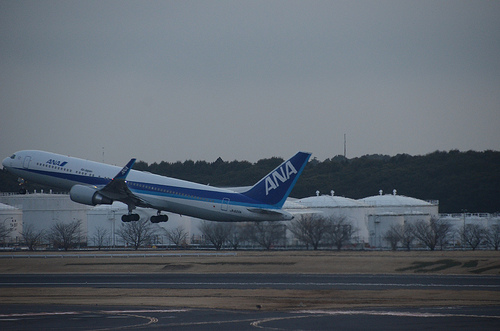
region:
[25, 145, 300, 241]
blue and white plane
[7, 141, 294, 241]
plane is taking off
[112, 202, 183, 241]
plane has black wheels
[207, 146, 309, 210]
blue and white tail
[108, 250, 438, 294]
runway is dark grey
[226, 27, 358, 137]
grey and hazy sky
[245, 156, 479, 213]
green trees behind plane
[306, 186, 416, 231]
white dome shaped buildings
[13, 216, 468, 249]
bare trees in front of domes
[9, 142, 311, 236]
the plane taking off the runway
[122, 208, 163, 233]
the landing gear of the plane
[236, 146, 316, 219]
the tail of the plane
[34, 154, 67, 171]
the logo on the plane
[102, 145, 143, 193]
the wing of the plane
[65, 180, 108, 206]
the engine under the plane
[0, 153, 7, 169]
the nose of the plane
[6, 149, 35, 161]
the cockpit of the plane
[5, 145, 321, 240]
the plane is blue and white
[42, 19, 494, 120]
the sky is gray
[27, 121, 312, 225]
blue and white plane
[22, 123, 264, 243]
plane is taking off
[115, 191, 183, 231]
black wheels on plane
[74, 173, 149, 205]
white engines on plane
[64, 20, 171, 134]
sky is blue and white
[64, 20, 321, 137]
thin clouds in sky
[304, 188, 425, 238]
white and domed buildings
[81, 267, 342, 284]
runway is dark grey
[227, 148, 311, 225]
blue and white tail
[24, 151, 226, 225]
blue stripe on plane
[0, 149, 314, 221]
An airplane in the air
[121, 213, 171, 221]
Wheels on the airplane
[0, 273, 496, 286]
The runway beneath the airplane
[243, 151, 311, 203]
The tail of the airplane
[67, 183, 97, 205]
An engine on the airplane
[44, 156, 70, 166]
An Ana logo on the airplane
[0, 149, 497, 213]
Trees near the white buildings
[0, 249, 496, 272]
Grass by the runway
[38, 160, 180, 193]
Windows on the airplane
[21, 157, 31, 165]
A door on the airplane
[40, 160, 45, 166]
glass window on the white plane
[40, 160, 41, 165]
glass window on the white plane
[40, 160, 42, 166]
glass window on the white plane